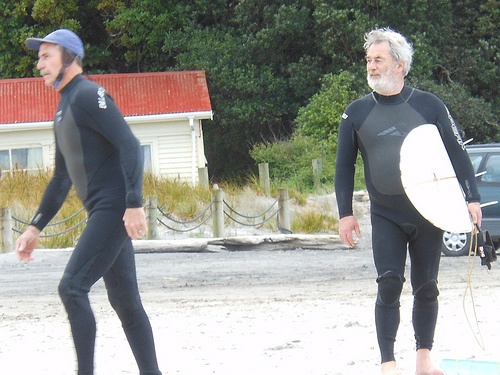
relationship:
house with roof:
[1, 65, 212, 228] [0, 62, 214, 125]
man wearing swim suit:
[13, 31, 161, 373] [29, 72, 165, 371]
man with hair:
[335, 24, 486, 373] [360, 25, 414, 93]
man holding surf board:
[335, 24, 486, 373] [398, 121, 488, 236]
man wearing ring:
[13, 31, 161, 373] [137, 228, 144, 236]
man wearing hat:
[13, 31, 161, 373] [22, 27, 88, 88]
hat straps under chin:
[22, 27, 88, 88] [46, 78, 65, 92]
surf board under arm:
[398, 121, 488, 236] [434, 90, 478, 208]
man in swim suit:
[13, 31, 161, 373] [29, 72, 165, 371]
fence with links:
[1, 184, 295, 252] [154, 199, 214, 237]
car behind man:
[435, 139, 500, 257] [335, 24, 486, 373]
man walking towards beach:
[13, 31, 161, 373] [2, 182, 500, 372]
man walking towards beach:
[335, 24, 486, 373] [2, 182, 500, 372]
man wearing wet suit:
[335, 24, 486, 373] [333, 84, 483, 362]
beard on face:
[364, 68, 397, 96] [363, 43, 405, 92]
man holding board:
[335, 24, 486, 373] [398, 121, 488, 236]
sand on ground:
[3, 189, 498, 368] [6, 185, 497, 372]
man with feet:
[335, 24, 486, 373] [379, 348, 451, 373]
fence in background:
[1, 184, 295, 252] [1, 3, 499, 266]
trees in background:
[3, 2, 500, 192] [1, 3, 499, 266]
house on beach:
[1, 65, 212, 228] [2, 182, 500, 372]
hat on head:
[22, 27, 88, 88] [35, 28, 89, 89]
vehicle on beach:
[438, 142, 500, 259] [2, 182, 500, 372]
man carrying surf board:
[13, 31, 161, 373] [398, 121, 488, 236]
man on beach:
[13, 31, 161, 373] [2, 182, 500, 372]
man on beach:
[335, 24, 486, 373] [2, 182, 500, 372]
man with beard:
[335, 24, 486, 373] [364, 68, 397, 96]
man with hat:
[13, 31, 161, 373] [22, 27, 88, 88]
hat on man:
[22, 27, 88, 88] [13, 31, 161, 373]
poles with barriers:
[2, 156, 329, 253] [13, 183, 280, 252]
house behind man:
[1, 65, 212, 228] [13, 31, 161, 373]